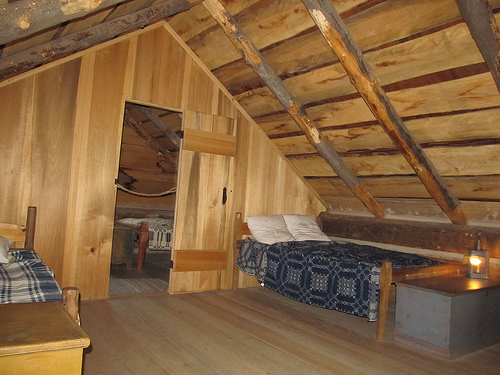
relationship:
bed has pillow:
[235, 214, 465, 345] [246, 214, 291, 245]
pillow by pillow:
[246, 214, 291, 245] [285, 214, 328, 243]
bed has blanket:
[235, 214, 465, 345] [268, 241, 444, 319]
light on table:
[465, 237, 488, 279] [396, 267, 500, 359]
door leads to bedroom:
[169, 112, 239, 294] [105, 103, 181, 294]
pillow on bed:
[246, 214, 291, 245] [235, 214, 465, 345]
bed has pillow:
[235, 214, 465, 345] [285, 214, 328, 243]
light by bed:
[465, 237, 488, 279] [235, 214, 465, 345]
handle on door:
[221, 188, 227, 203] [169, 112, 239, 294]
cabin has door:
[1, 1, 500, 375] [169, 112, 239, 294]